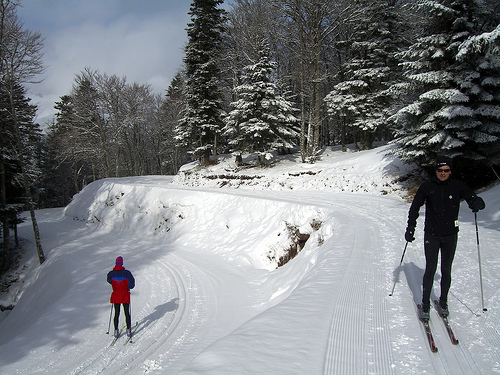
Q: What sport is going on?
A: Skiing.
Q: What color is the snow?
A: White.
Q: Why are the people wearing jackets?
A: It's cold.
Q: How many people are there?
A: 2.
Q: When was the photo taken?
A: Daytime.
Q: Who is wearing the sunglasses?
A: Man in all black.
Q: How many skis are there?
A: 4.